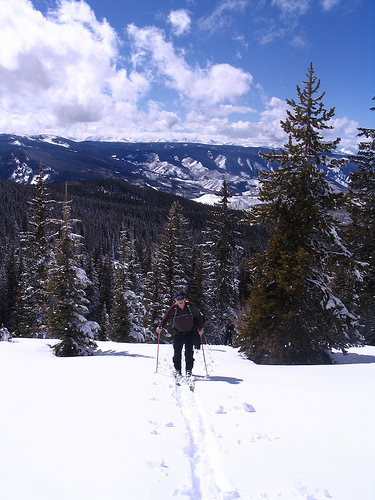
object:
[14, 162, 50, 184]
snow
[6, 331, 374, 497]
ground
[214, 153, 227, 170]
snow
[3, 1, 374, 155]
clouds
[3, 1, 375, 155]
sky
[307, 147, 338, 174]
ground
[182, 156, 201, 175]
snow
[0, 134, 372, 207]
mountains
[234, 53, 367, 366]
tall tree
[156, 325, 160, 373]
ski poles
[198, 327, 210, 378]
ski poles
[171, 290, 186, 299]
hat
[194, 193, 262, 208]
snow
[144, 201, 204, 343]
tree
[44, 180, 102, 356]
tree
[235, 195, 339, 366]
tree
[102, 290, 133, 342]
tree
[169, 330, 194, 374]
pants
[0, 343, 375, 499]
snow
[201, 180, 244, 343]
tree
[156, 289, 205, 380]
man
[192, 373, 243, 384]
shade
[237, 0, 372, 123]
blue sky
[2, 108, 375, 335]
snowy forest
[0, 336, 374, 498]
hill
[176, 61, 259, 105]
cow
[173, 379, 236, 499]
ski path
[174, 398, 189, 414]
track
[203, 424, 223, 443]
track